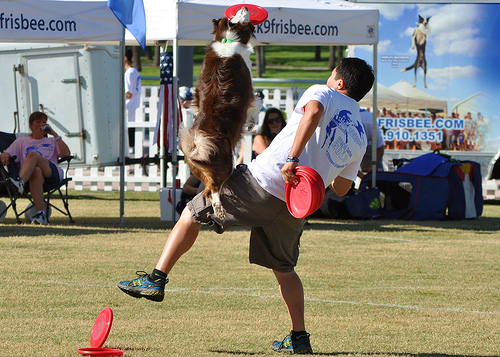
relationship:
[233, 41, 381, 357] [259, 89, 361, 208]
man wearing shirt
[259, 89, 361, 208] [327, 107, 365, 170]
shirt has graphic print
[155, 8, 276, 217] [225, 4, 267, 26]
dog caught frisbee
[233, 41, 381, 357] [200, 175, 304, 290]
man wearing shorts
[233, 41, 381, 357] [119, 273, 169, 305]
man wearing sneakers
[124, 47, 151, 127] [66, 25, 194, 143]
man in background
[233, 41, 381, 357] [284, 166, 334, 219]
man holding frisbees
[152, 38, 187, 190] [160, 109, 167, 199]
flag on a pole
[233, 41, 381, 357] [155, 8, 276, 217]
man playing with dog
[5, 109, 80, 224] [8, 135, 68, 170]
woman wearing shirt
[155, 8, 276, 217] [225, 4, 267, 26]
dog playing frisbee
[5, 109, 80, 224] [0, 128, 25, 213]
woman sitting in chair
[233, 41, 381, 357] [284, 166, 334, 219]
man has frisbees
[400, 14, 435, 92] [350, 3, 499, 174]
dog on sign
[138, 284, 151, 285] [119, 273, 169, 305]
part of sneakers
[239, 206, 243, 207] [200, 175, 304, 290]
part of shorts